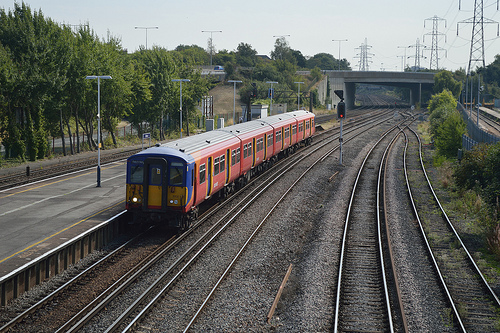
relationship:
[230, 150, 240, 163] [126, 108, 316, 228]
window on train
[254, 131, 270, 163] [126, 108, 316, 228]
window on train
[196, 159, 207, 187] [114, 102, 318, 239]
window on train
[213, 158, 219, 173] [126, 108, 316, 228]
window part of train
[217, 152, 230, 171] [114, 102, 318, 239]
window part of train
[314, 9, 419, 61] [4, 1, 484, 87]
clouds in sky